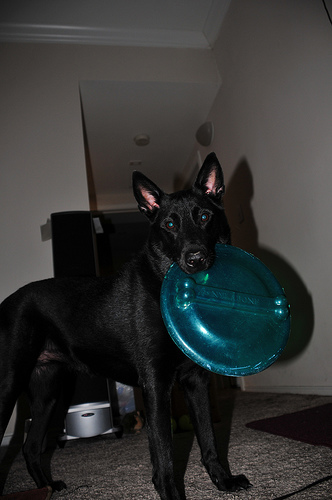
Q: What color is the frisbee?
A: Green.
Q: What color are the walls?
A: White.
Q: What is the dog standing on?
A: Rug.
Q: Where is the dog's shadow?
A: On wall.